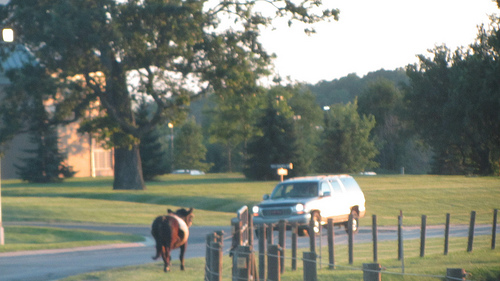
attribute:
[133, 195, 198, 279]
animal — brown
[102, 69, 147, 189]
trunk — thick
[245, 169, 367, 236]
car — moving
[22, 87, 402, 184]
pine trees — short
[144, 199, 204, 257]
animal — running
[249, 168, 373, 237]
vehicle — older style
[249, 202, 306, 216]
headlights — turned on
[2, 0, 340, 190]
tree — tall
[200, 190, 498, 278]
fence — short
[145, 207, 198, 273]
cow — brown, large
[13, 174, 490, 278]
grass — short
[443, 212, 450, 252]
pole — brown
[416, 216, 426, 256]
pole — brown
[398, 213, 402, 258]
pole — brown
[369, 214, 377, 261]
pole — brown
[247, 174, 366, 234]
car — white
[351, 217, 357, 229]
rim — brown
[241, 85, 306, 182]
tree — tall, triangle, pine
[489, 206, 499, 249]
pole — wooden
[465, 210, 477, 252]
pole — wooden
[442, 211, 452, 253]
pole — wooden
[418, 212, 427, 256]
pole — wooden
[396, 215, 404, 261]
pole — wooden